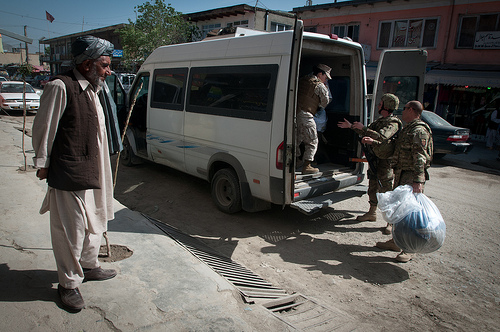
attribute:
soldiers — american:
[279, 54, 451, 267]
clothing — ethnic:
[26, 77, 135, 289]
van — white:
[118, 31, 363, 216]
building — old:
[283, 3, 499, 153]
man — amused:
[31, 39, 145, 311]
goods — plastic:
[375, 188, 459, 255]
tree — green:
[118, 1, 209, 148]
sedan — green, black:
[327, 95, 472, 161]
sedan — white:
[2, 65, 44, 113]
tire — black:
[200, 159, 246, 222]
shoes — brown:
[54, 256, 120, 315]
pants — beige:
[40, 180, 123, 293]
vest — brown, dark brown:
[47, 74, 123, 196]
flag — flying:
[40, 11, 61, 26]